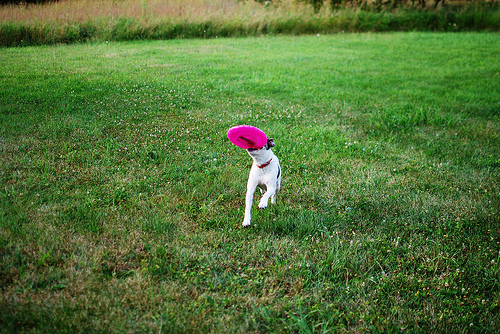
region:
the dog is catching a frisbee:
[226, 103, 288, 235]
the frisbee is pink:
[226, 121, 275, 171]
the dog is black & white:
[228, 110, 296, 245]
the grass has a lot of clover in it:
[48, 71, 191, 256]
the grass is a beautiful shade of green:
[57, 62, 156, 174]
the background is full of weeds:
[35, 2, 381, 26]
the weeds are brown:
[27, 0, 322, 31]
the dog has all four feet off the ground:
[204, 120, 324, 273]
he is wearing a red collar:
[233, 139, 293, 179]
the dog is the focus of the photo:
[204, 110, 301, 250]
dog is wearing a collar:
[228, 135, 303, 242]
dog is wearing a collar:
[222, 148, 282, 185]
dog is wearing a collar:
[247, 147, 280, 181]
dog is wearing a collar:
[240, 153, 295, 184]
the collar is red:
[230, 132, 286, 191]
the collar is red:
[246, 152, 275, 177]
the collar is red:
[243, 160, 300, 187]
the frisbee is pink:
[215, 111, 290, 198]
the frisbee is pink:
[184, 90, 286, 182]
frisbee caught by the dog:
[173, 95, 324, 269]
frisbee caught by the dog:
[210, 116, 292, 226]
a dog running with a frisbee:
[220, 125, 290, 224]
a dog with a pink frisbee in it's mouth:
[211, 117, 293, 228]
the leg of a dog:
[236, 180, 256, 234]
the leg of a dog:
[257, 183, 275, 210]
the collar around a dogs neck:
[251, 154, 276, 171]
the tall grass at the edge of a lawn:
[7, 5, 418, 48]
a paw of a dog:
[234, 215, 254, 230]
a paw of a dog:
[254, 193, 273, 215]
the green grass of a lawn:
[344, 169, 427, 265]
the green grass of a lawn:
[80, 63, 176, 133]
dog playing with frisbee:
[160, 85, 306, 240]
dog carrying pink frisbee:
[179, 109, 321, 261]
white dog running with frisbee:
[210, 110, 320, 220]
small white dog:
[180, 90, 295, 235]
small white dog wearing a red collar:
[200, 105, 315, 230]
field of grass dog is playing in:
[5, 41, 495, 326]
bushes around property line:
[0, 10, 440, 50]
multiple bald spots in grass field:
[95, 40, 237, 80]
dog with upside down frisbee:
[193, 108, 315, 233]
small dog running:
[207, 96, 296, 235]